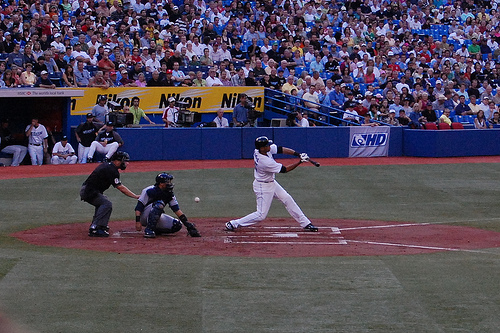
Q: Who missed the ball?
A: The batter.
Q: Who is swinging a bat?
A: Baseball player.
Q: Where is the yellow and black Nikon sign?
A: Behind the players.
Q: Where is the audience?
A: At a baseball game.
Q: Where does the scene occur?
A: Outdoors on a man-made facility.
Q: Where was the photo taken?
A: At a baseball stadium.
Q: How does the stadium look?
A: Packed to capacity.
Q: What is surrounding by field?
A: Home plate.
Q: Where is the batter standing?
A: Batter's box.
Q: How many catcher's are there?
A: One.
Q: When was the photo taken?
A: Day time.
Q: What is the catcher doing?
A: Catching.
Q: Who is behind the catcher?
A: Umpire.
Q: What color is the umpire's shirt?
A: Blue.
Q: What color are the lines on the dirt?
A: White.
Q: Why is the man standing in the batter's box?
A: He is batting.